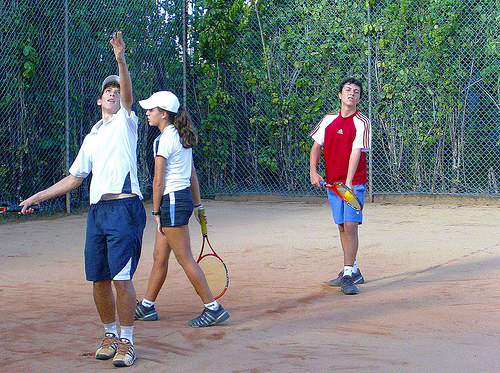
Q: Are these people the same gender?
A: No, they are both male and female.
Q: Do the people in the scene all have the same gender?
A: No, they are both male and female.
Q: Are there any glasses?
A: No, there are no glasses.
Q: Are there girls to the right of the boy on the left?
A: Yes, there is a girl to the right of the boy.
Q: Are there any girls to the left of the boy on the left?
A: No, the girl is to the right of the boy.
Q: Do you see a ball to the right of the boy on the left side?
A: No, there is a girl to the right of the boy.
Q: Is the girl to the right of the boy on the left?
A: Yes, the girl is to the right of the boy.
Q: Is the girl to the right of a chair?
A: No, the girl is to the right of the boy.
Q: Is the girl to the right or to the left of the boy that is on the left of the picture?
A: The girl is to the right of the boy.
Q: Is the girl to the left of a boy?
A: Yes, the girl is to the left of a boy.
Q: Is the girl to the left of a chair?
A: No, the girl is to the left of a boy.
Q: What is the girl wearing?
A: The girl is wearing a shirt.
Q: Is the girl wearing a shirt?
A: Yes, the girl is wearing a shirt.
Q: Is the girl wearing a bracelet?
A: No, the girl is wearing a shirt.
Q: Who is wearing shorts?
A: The boy is wearing shorts.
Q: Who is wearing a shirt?
A: The boy is wearing a shirt.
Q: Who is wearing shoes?
A: The boy is wearing shoes.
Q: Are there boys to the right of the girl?
A: Yes, there is a boy to the right of the girl.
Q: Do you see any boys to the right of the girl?
A: Yes, there is a boy to the right of the girl.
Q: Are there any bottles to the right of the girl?
A: No, there is a boy to the right of the girl.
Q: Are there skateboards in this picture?
A: No, there are no skateboards.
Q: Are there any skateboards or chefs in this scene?
A: No, there are no skateboards or chefs.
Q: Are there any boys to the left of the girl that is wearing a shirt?
A: Yes, there is a boy to the left of the girl.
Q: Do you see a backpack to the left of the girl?
A: No, there is a boy to the left of the girl.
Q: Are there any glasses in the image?
A: No, there are no glasses.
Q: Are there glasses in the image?
A: No, there are no glasses.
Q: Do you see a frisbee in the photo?
A: No, there are no frisbees.